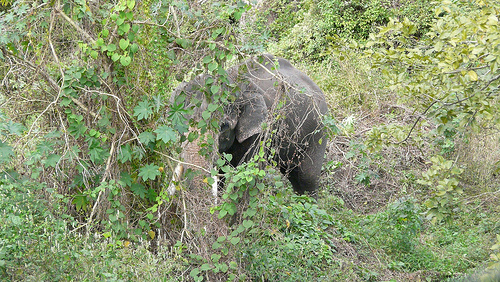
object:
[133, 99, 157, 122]
leaves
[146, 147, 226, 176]
branch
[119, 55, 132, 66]
leaves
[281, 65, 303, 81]
skin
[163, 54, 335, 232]
elephant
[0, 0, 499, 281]
bushes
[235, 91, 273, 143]
ear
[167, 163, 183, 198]
tusk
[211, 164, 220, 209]
tusk